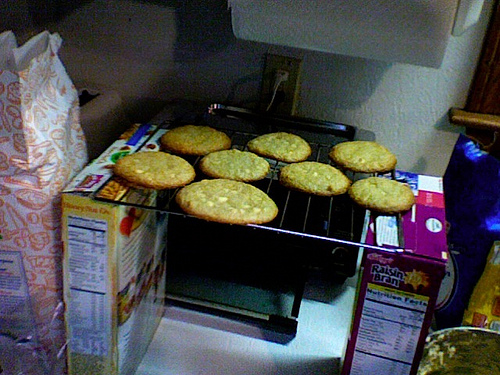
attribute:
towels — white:
[228, 0, 445, 71]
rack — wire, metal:
[92, 121, 402, 251]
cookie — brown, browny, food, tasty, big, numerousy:
[178, 175, 280, 227]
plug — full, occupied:
[260, 54, 301, 115]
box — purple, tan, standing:
[341, 170, 444, 373]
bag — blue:
[434, 131, 499, 325]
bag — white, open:
[0, 30, 90, 374]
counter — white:
[126, 270, 361, 374]